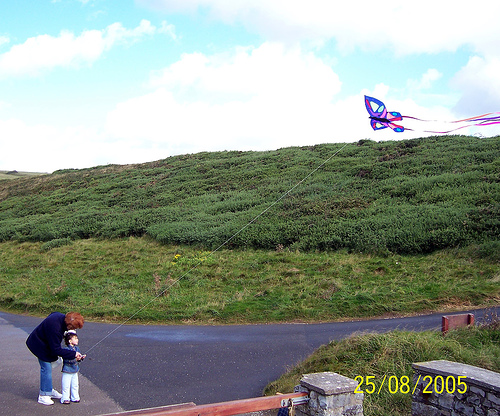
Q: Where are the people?
A: In a road.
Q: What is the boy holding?
A: A kite.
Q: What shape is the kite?
A: A butterfly.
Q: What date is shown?
A: 25/08/2005.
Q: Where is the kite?
A: In the air.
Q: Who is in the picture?
A: A woman and a child.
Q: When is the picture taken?
A: Daytime.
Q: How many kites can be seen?
A: 1.